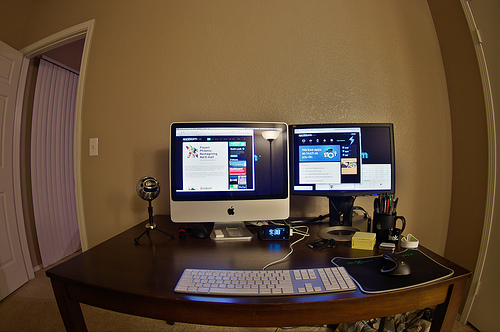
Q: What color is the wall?
A: Beige.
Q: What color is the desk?
A: Brown.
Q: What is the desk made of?
A: Wood.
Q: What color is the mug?
A: Black.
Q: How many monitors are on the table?
A: 2.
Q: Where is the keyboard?
A: On the desk.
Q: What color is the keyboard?
A: White.